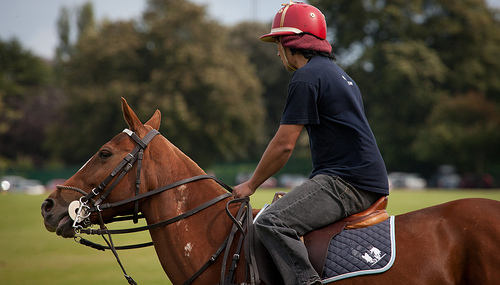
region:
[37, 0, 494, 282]
a rider exercising a horse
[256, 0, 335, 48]
horse exerciser is wearing a red helmet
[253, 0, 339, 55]
it looks like he has a rag on under the helmet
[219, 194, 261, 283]
this stirrup is folded up rather than hanging down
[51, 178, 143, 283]
the horse is wearing a rope as well as a harness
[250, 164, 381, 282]
horse exerciser is wearing gray pants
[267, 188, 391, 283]
saddle is a small racing saddle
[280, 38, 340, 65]
horse exerciser has black curly hair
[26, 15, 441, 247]
this is man on horseback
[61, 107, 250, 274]
this a horse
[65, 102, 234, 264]
the horse has a bridle on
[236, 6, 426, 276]
this man is a jockey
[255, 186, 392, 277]
this is a saddle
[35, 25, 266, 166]
the background is blurry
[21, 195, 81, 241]
the nose is dark brown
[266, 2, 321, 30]
the man is wearing a helmet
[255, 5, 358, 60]
the man's helmet is red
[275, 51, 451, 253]
the man has a tshirt on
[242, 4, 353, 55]
a red helmet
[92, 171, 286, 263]
the reins are black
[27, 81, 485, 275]
this horse is brwon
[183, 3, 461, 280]
a guy is riding a horse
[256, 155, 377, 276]
a black pair of jeans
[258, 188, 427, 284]
the saddle is brown leather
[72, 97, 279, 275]
leather reins on a horse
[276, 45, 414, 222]
a dark navy blue tee shirt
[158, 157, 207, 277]
white spots on the horse's neck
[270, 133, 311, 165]
this is an elbow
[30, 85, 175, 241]
a head of a horse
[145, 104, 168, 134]
the ear of a horse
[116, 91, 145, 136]
the ear of a horse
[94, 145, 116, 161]
the eye of a horse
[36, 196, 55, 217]
the nose of a horse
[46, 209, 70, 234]
the mouth of a horse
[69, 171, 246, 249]
the rains of a bridle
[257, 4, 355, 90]
a man wearing a red helmet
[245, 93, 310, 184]
the arm of a man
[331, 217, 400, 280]
a saddle blanket on a horse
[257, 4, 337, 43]
red helmet on head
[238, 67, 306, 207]
the man's left arm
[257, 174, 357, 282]
the man's left leg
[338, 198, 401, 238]
brown saddle on the horse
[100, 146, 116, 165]
left eye on the horse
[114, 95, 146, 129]
left brown ear on horse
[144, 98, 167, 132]
right brown ear on horse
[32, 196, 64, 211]
nostril on the horse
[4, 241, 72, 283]
green grass on the ground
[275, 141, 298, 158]
elbow on the man